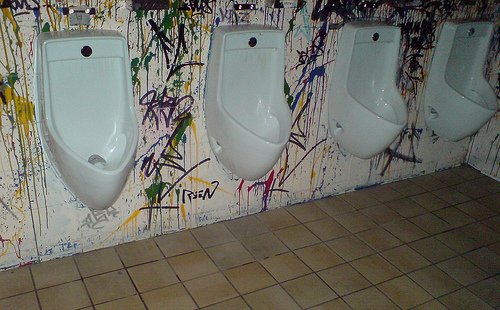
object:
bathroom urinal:
[29, 25, 146, 232]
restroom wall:
[127, 22, 224, 210]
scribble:
[116, 47, 207, 208]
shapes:
[269, 208, 478, 300]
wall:
[18, 31, 478, 183]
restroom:
[9, 28, 497, 301]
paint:
[132, 14, 204, 222]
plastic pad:
[75, 151, 112, 177]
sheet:
[56, 1, 101, 30]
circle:
[78, 42, 91, 55]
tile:
[120, 232, 250, 306]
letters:
[170, 176, 225, 206]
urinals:
[25, 18, 497, 186]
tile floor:
[4, 160, 497, 304]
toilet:
[23, 20, 153, 231]